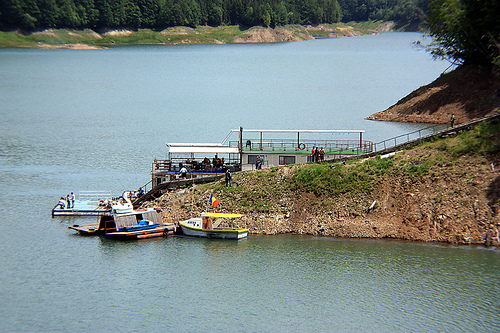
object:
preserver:
[449, 114, 455, 129]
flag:
[209, 193, 221, 207]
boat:
[175, 194, 249, 240]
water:
[2, 19, 498, 329]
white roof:
[168, 142, 235, 152]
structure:
[163, 142, 240, 169]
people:
[180, 155, 230, 169]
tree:
[415, 29, 499, 119]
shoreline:
[143, 158, 499, 249]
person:
[66, 194, 71, 209]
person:
[71, 192, 76, 209]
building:
[148, 128, 369, 186]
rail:
[227, 139, 376, 155]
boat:
[106, 190, 135, 214]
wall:
[242, 154, 354, 171]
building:
[152, 127, 371, 187]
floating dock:
[52, 185, 123, 220]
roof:
[170, 141, 236, 154]